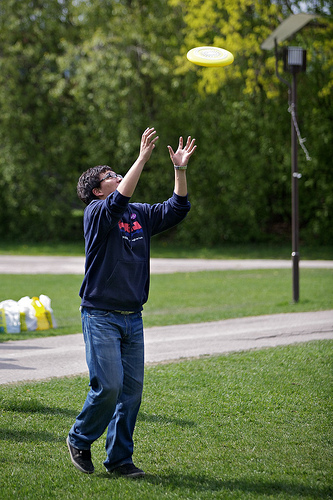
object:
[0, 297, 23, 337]
bags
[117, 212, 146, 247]
writing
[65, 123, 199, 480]
man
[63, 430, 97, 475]
shoes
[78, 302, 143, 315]
belt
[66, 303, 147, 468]
jeans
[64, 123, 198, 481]
boy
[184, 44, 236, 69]
frisbee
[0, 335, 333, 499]
grass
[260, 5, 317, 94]
panel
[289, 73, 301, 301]
pole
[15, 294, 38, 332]
bags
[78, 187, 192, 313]
sweatshirt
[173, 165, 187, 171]
watch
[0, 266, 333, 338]
grass